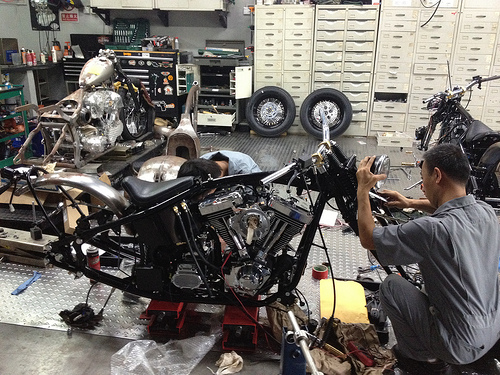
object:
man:
[339, 145, 499, 373]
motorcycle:
[10, 108, 394, 350]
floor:
[0, 137, 425, 373]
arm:
[356, 188, 426, 247]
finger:
[354, 153, 379, 166]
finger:
[366, 153, 373, 168]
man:
[355, 144, 498, 374]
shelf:
[1, 61, 62, 71]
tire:
[298, 86, 352, 140]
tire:
[242, 84, 295, 138]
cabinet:
[251, 0, 314, 134]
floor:
[288, 107, 331, 146]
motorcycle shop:
[0, 0, 499, 374]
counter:
[0, 62, 70, 72]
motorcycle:
[414, 73, 499, 204]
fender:
[12, 171, 135, 210]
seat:
[120, 171, 198, 204]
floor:
[184, 280, 388, 367]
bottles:
[21, 50, 39, 68]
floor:
[27, 256, 445, 358]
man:
[348, 146, 484, 372]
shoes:
[387, 345, 451, 375]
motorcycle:
[12, 49, 165, 171]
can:
[9, 51, 22, 66]